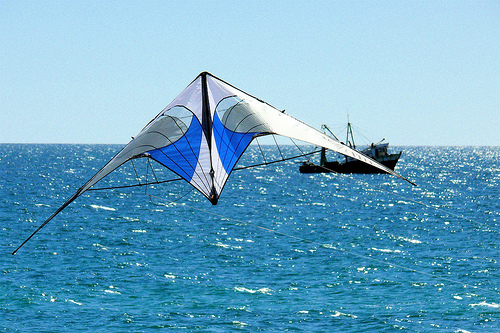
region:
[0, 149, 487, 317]
A large body of water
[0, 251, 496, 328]
Ripples in the water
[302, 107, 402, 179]
A ship in the water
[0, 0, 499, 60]
A light blue sky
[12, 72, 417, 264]
A kite in the air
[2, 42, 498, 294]
A natural landscape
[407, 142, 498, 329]
Shiny reflection on the water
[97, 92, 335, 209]
Blue, gray, and white colors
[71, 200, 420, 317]
Moving water effects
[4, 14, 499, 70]
A clear sky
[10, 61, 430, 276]
Kite on the air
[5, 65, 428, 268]
Kite form is stunt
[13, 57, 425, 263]
Kite is white, blue and gray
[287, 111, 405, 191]
Ship in the ocean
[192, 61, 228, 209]
Spine of kite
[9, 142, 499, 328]
Ocean is blue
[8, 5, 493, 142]
Sky is blue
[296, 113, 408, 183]
Ship is black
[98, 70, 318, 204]
Spreader of kite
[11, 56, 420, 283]
Kite is flying in the air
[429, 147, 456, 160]
furthest part of the sea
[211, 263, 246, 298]
ripples of ocean wwater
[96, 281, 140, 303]
section of the oceans water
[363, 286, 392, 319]
part of the sea water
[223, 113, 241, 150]
section of a kite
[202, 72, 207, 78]
edge of a kite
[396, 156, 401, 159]
front part of a boat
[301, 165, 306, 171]
back part of a boat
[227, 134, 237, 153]
blue section of a kite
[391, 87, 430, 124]
section of the sky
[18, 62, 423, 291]
a big blue and white kite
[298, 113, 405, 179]
a small boat in the background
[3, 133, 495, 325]
a blue stretch of ocean with small waves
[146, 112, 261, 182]
two blue triangles on the kite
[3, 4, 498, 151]
a cloudless blue sky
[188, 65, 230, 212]
a black stripe down the center of the kite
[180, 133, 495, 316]
two barely visible white strings attached to the kite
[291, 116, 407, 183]
a boat passing by in front of the kite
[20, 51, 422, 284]
a large kite being flown over the ocean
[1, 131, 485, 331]
a calm blue ocean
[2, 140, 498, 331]
Water is brilliant blue.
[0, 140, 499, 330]
Water sparkles in the sunshine.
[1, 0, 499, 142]
Sky is completely clear.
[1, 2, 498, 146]
Sky is free of clouds.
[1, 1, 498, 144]
Sky is light blue in color.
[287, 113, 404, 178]
Ship sailing on the waters.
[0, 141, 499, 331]
The water is very tranquil.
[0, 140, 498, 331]
Small ripples spread across the water.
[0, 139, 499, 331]
The water appears slightly choppy.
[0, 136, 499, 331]
The water has a soothing effect.